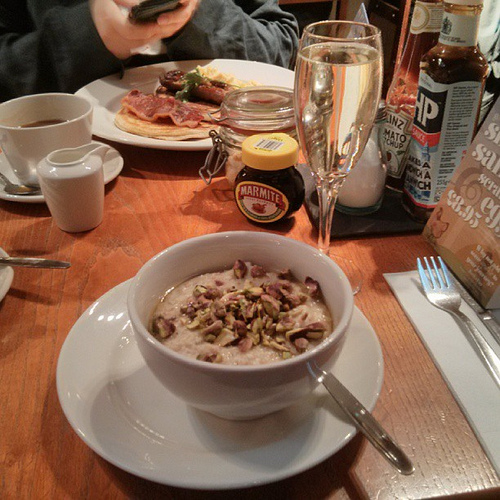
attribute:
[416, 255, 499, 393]
fork — silver, metal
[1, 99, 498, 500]
table — wooden, brown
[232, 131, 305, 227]
marmite — small, present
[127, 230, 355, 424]
bowl — small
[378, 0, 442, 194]
ketchup bottle — present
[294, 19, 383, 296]
wine glass — full, clear, present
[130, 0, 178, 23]
cellphone — black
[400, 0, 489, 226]
steak sauce bottle — present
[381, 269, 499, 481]
napkin — white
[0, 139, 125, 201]
saucer — white, small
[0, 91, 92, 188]
cup — white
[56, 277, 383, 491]
plate — white, round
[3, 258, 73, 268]
utensil handle — silver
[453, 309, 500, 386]
handle — silver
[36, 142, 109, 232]
creamer dish — porcelain, tiny, small, white